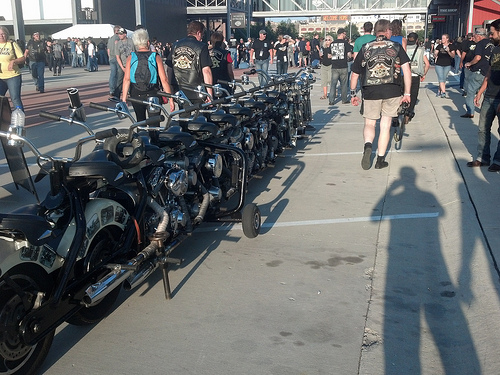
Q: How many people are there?
A: 25.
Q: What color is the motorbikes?
A: Gray and black.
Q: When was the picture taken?
A: In the daytime.